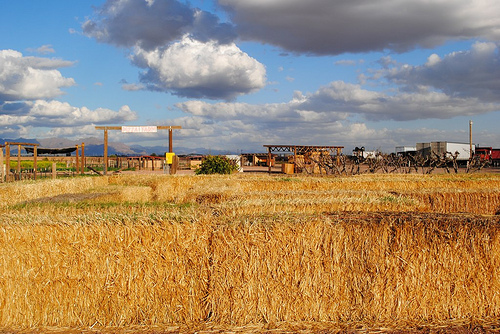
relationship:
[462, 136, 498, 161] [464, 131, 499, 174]
cab on truck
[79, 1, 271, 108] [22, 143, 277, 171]
clouds on mountains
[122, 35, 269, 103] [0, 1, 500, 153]
clouds in blue skies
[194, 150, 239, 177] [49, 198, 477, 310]
tree in field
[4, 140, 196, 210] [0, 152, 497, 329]
plants in field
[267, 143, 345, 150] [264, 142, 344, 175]
top of shade